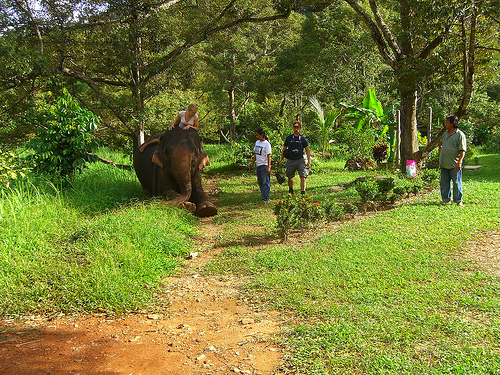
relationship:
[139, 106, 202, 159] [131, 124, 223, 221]
woman riding elephant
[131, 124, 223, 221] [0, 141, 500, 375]
elephant in grass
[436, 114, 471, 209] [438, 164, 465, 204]
man wears jeans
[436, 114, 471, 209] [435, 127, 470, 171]
man wears shirt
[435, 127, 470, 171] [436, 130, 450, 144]
shirt has sleeve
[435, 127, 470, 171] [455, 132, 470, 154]
shirt has sleeve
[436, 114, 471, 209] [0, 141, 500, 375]
man in grass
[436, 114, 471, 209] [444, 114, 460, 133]
man has hair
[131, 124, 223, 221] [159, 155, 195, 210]
elephant has trunk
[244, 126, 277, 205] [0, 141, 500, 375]
woman in grass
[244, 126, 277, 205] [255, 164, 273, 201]
woman wears jeans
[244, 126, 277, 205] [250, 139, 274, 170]
woman wears shirt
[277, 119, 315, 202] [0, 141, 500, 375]
man in grass